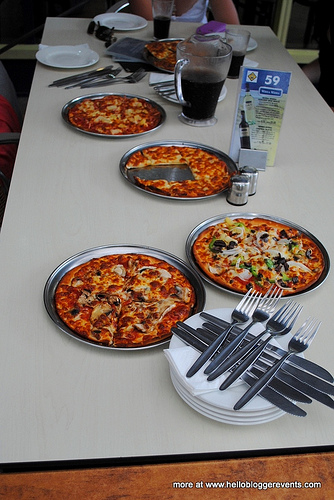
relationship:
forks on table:
[184, 288, 321, 416] [6, 15, 332, 466]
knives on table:
[169, 310, 333, 418] [6, 15, 332, 466]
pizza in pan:
[51, 253, 193, 346] [43, 243, 205, 351]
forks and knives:
[184, 288, 321, 416] [169, 310, 333, 418]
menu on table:
[229, 67, 292, 172] [6, 15, 332, 466]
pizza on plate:
[51, 253, 193, 346] [43, 243, 205, 351]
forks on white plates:
[184, 288, 321, 416] [166, 306, 300, 423]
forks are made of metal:
[184, 288, 321, 416] [184, 289, 321, 410]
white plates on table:
[166, 306, 300, 423] [6, 15, 332, 466]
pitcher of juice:
[170, 36, 230, 126] [175, 71, 228, 119]